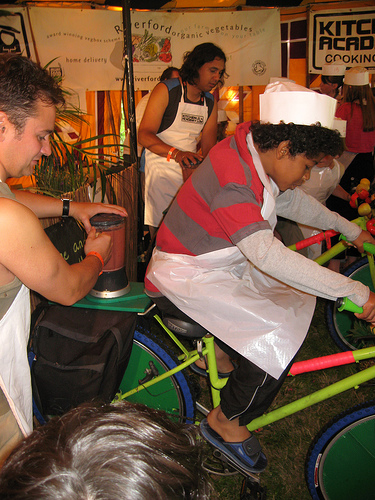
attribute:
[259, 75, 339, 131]
hat — white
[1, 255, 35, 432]
apron — white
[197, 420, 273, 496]
sandal — black, blue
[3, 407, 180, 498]
head — here, shiny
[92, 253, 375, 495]
bike — pink, colorful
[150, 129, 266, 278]
shirt — striped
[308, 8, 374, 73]
sign — black, white, written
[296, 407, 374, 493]
wheel — blue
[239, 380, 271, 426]
stripe — white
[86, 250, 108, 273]
bracelet — orange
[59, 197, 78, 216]
watch — black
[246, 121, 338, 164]
hair — sticking out, short, curly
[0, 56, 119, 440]
man — standing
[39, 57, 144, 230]
leaves — green